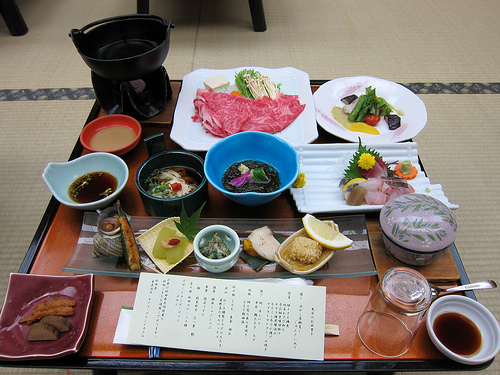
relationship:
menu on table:
[122, 267, 330, 364] [4, 72, 492, 369]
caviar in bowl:
[220, 159, 282, 194] [208, 127, 305, 197]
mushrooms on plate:
[242, 72, 282, 98] [166, 39, 336, 167]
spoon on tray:
[414, 278, 495, 295] [14, 78, 487, 372]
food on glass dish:
[241, 224, 281, 268] [336, 250, 376, 274]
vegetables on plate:
[333, 85, 408, 133] [295, 68, 432, 150]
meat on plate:
[183, 81, 311, 136] [171, 65, 319, 152]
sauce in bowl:
[39, 164, 134, 208] [39, 150, 128, 205]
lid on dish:
[378, 190, 456, 250] [381, 230, 445, 264]